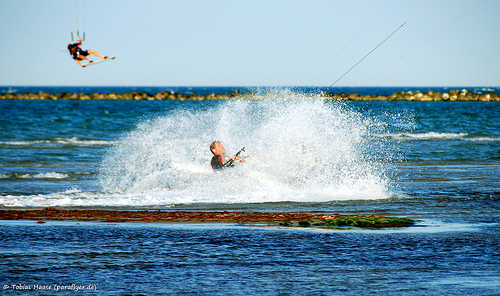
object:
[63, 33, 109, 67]
man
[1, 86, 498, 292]
water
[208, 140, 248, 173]
man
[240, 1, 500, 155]
rope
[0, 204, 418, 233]
moat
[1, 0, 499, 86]
sky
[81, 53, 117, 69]
water skii board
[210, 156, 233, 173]
wetsuit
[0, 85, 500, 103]
barrier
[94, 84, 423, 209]
splash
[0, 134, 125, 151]
wave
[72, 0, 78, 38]
string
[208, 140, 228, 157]
head